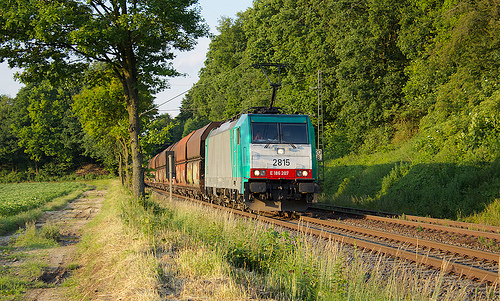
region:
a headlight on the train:
[251, 166, 261, 180]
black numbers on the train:
[269, 153, 294, 169]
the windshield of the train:
[249, 115, 281, 145]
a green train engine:
[201, 105, 326, 206]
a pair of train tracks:
[142, 177, 499, 287]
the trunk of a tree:
[116, 67, 151, 205]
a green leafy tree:
[71, 61, 149, 173]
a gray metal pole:
[312, 66, 329, 166]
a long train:
[143, 102, 323, 212]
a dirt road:
[0, 177, 115, 298]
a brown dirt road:
[0, 182, 111, 298]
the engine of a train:
[199, 109, 322, 215]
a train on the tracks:
[143, 106, 323, 217]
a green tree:
[71, 61, 159, 153]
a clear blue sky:
[0, 0, 258, 134]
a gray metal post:
[311, 61, 330, 184]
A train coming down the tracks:
[132, 108, 321, 220]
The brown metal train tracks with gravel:
[138, 174, 498, 299]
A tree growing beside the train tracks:
[1, 0, 209, 207]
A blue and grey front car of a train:
[198, 111, 323, 214]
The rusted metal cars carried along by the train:
[136, 122, 221, 201]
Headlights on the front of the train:
[246, 165, 313, 178]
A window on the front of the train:
[246, 117, 312, 147]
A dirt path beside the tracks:
[0, 185, 120, 299]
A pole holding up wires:
[246, 56, 307, 115]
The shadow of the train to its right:
[294, 157, 497, 222]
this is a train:
[185, 113, 300, 195]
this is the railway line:
[330, 218, 392, 269]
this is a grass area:
[107, 223, 203, 287]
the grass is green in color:
[178, 217, 213, 237]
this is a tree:
[66, 18, 161, 127]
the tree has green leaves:
[32, 8, 71, 24]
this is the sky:
[3, 72, 13, 90]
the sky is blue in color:
[206, 3, 228, 10]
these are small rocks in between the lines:
[368, 217, 383, 229]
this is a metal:
[357, 233, 382, 257]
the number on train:
[265, 154, 303, 171]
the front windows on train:
[251, 119, 314, 146]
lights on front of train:
[250, 165, 275, 180]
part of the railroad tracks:
[309, 215, 415, 248]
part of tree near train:
[90, 4, 183, 187]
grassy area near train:
[9, 179, 56, 203]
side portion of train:
[207, 137, 230, 179]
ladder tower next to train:
[317, 67, 333, 145]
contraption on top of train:
[253, 50, 287, 113]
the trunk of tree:
[132, 157, 149, 202]